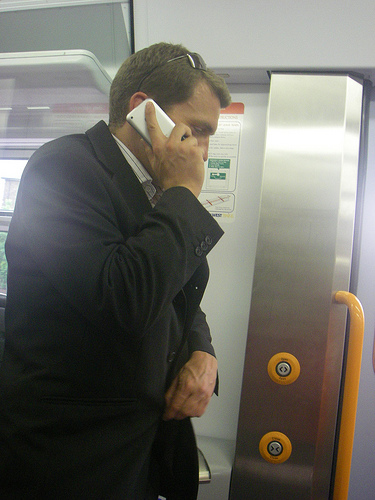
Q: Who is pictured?
A: A man.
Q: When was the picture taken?
A: Daytime.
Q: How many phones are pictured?
A: One.